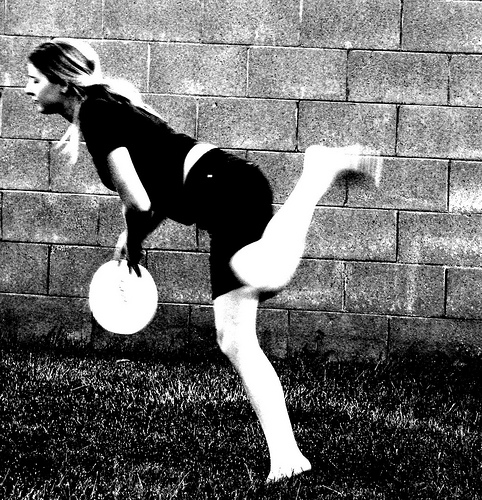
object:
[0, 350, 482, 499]
grass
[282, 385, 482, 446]
line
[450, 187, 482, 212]
chalk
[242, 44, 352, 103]
tiles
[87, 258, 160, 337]
frisbee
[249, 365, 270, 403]
skin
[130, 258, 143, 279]
fingers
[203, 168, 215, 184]
spot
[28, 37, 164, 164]
hair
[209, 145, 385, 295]
leg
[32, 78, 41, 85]
eye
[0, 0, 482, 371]
wall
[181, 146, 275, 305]
shorts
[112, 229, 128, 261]
hand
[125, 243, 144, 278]
hand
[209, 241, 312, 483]
leg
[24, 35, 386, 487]
person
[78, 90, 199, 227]
clothing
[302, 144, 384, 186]
foot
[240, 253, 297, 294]
knee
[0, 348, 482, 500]
ground